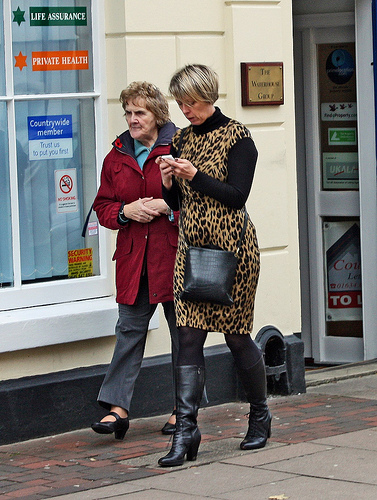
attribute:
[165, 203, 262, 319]
handbag — that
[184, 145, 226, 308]
dress — animal print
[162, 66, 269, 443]
woman — blonde, looking down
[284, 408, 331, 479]
sidewalk — mixed brick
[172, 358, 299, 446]
boots — high heeled, black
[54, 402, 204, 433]
shoes — mary jane shoes, high heeled, black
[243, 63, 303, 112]
plaque — brass, wood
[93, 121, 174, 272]
coat — red, blue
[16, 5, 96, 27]
sticker — green, white, business ad, red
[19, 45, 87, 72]
sticker — red, white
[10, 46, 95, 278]
window — white trimmed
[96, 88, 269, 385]
women — walking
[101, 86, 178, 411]
lady — that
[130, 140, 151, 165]
blue shirt — that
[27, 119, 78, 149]
sign — blue, white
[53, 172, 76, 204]
sign — red white, black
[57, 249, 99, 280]
sticker — red black, yellow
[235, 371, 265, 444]
boot — that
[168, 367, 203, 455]
boot — that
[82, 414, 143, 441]
shoe — that